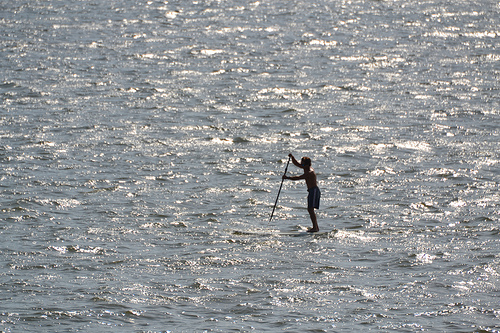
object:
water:
[1, 1, 499, 331]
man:
[281, 153, 320, 232]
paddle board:
[233, 224, 365, 236]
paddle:
[269, 155, 292, 221]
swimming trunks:
[307, 185, 321, 209]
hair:
[301, 156, 311, 166]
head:
[301, 156, 312, 168]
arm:
[288, 153, 303, 168]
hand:
[287, 153, 292, 157]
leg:
[307, 207, 318, 232]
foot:
[306, 227, 319, 232]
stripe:
[312, 188, 317, 208]